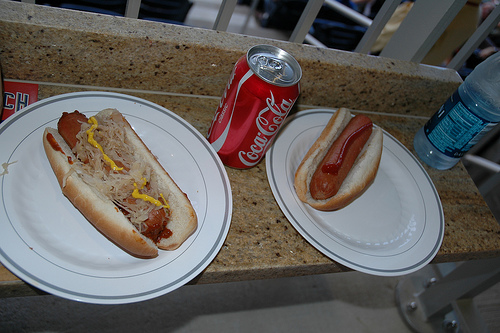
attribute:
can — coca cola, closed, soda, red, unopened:
[204, 44, 302, 170]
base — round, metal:
[395, 263, 462, 333]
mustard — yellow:
[86, 116, 124, 173]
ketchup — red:
[320, 121, 375, 175]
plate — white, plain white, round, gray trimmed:
[0, 91, 235, 304]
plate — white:
[265, 107, 446, 279]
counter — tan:
[0, 1, 499, 299]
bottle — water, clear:
[412, 50, 498, 170]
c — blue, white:
[2, 90, 15, 109]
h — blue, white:
[14, 90, 30, 113]